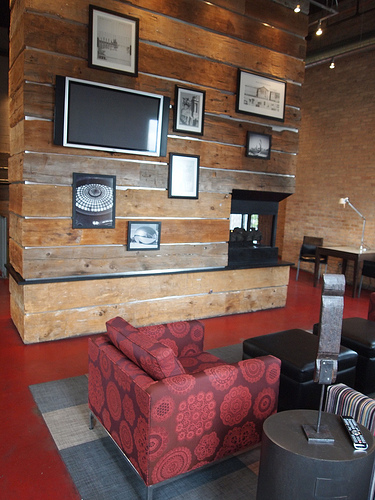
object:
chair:
[86, 320, 279, 486]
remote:
[340, 416, 369, 451]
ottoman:
[241, 329, 357, 410]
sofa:
[324, 383, 375, 431]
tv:
[53, 75, 169, 158]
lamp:
[300, 275, 344, 444]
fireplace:
[227, 190, 289, 270]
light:
[316, 29, 322, 35]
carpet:
[29, 343, 256, 500]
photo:
[88, 5, 138, 78]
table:
[313, 246, 374, 298]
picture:
[235, 68, 287, 122]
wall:
[26, 2, 305, 282]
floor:
[0, 268, 369, 500]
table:
[256, 409, 374, 500]